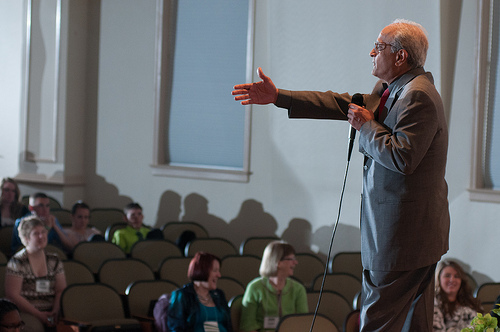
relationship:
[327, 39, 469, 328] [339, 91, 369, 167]
man with a mic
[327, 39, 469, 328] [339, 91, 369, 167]
man with mic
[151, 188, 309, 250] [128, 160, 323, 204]
shadows on wall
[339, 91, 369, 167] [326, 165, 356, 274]
mic has cord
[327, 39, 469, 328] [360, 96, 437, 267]
man wearing coat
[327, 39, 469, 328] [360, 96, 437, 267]
man wearing a coat